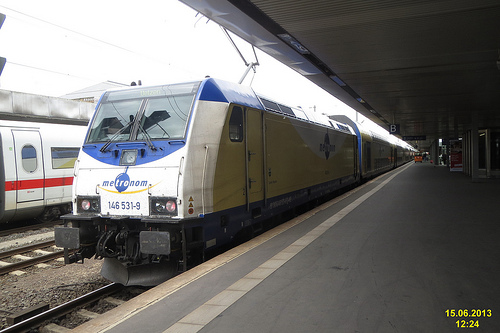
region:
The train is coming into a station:
[30, 32, 470, 278]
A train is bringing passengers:
[26, 35, 463, 325]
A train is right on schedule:
[31, 60, 476, 305]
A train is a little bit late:
[51, 27, 468, 292]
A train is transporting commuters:
[20, 27, 490, 320]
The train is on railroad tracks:
[23, 36, 473, 286]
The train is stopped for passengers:
[35, 51, 460, 281]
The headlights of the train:
[145, 191, 176, 211]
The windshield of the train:
[142, 95, 185, 137]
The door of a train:
[242, 106, 264, 196]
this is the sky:
[23, 14, 140, 75]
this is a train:
[99, 93, 302, 207]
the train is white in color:
[182, 150, 206, 200]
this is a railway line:
[45, 293, 97, 319]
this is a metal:
[48, 297, 68, 314]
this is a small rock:
[40, 277, 60, 291]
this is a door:
[243, 107, 262, 201]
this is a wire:
[23, 15, 92, 47]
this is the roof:
[325, 10, 466, 118]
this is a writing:
[441, 300, 496, 330]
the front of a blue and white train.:
[36, 53, 220, 246]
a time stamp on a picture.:
[442, 301, 496, 331]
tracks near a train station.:
[3, 263, 149, 331]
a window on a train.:
[128, 85, 195, 145]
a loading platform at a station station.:
[99, 140, 498, 331]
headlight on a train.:
[139, 182, 188, 219]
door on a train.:
[9, 120, 48, 216]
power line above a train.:
[196, 0, 264, 91]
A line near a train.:
[159, 151, 421, 330]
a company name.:
[90, 168, 151, 196]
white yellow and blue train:
[112, 96, 390, 186]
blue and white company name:
[87, 160, 171, 212]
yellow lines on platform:
[129, 141, 459, 330]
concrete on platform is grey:
[202, 185, 447, 298]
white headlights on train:
[77, 192, 179, 214]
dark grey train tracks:
[19, 231, 108, 331]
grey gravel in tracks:
[0, 228, 130, 315]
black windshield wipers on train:
[96, 96, 186, 154]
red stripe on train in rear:
[18, 173, 68, 200]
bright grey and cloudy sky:
[40, 8, 157, 73]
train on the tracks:
[62, 78, 448, 277]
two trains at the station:
[0, 1, 485, 331]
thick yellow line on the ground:
[72, 274, 162, 331]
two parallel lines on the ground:
[65, 146, 420, 332]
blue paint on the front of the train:
[87, 146, 182, 166]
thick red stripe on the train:
[2, 168, 78, 198]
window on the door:
[18, 143, 40, 175]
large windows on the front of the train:
[83, 91, 196, 155]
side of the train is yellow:
[212, 107, 389, 209]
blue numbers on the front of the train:
[103, 196, 142, 212]